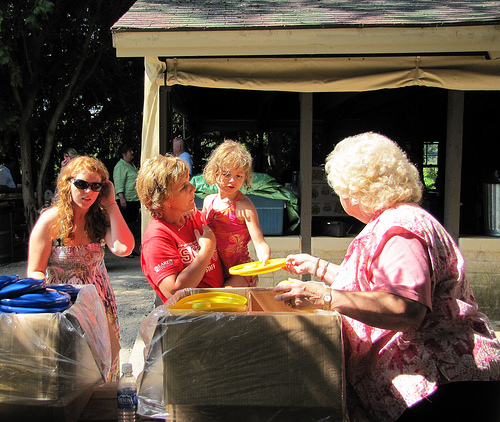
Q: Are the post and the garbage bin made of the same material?
A: No, the post is made of wood and the garbage bin is made of metal.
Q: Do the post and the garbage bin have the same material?
A: No, the post is made of wood and the garbage bin is made of metal.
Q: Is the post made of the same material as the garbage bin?
A: No, the post is made of wood and the garbage bin is made of metal.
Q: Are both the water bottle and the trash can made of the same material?
A: No, the water bottle is made of plastic and the trash can is made of metal.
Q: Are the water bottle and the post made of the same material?
A: No, the water bottle is made of plastic and the post is made of wood.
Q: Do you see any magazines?
A: No, there are no magazines.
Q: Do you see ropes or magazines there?
A: No, there are no magazines or ropes.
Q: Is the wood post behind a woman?
A: Yes, the post is behind a woman.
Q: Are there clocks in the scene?
A: No, there are no clocks.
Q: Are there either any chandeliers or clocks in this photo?
A: No, there are no clocks or chandeliers.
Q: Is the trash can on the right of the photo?
A: Yes, the trash can is on the right of the image.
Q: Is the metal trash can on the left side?
A: No, the garbage can is on the right of the image.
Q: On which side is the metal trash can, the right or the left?
A: The trashcan is on the right of the image.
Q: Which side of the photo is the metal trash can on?
A: The garbage can is on the right of the image.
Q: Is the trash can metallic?
A: Yes, the trash can is metallic.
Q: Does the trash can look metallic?
A: Yes, the trash can is metallic.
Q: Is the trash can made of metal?
A: Yes, the trash can is made of metal.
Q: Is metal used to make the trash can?
A: Yes, the trash can is made of metal.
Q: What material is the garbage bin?
A: The garbage bin is made of metal.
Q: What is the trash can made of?
A: The garbage bin is made of metal.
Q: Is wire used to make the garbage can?
A: No, the garbage can is made of metal.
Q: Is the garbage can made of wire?
A: No, the garbage can is made of metal.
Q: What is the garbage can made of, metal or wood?
A: The garbage can is made of metal.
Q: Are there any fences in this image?
A: No, there are no fences.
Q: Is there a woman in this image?
A: Yes, there is a woman.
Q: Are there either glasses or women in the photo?
A: Yes, there is a woman.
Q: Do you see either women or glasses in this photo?
A: Yes, there is a woman.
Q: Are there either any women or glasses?
A: Yes, there is a woman.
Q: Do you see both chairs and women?
A: No, there is a woman but no chairs.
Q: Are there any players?
A: No, there are no players.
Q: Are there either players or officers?
A: No, there are no players or officers.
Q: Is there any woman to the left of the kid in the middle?
A: Yes, there is a woman to the left of the kid.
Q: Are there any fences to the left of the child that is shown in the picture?
A: No, there is a woman to the left of the child.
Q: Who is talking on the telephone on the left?
A: The woman is talking on the phone.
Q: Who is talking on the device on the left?
A: The woman is talking on the phone.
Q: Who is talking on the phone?
A: The woman is talking on the phone.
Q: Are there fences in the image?
A: No, there are no fences.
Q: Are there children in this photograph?
A: Yes, there is a child.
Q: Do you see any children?
A: Yes, there is a child.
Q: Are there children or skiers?
A: Yes, there is a child.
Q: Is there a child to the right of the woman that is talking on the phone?
A: Yes, there is a child to the right of the woman.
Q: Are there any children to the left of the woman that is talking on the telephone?
A: No, the child is to the right of the woman.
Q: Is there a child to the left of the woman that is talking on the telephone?
A: No, the child is to the right of the woman.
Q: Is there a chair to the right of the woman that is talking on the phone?
A: No, there is a child to the right of the woman.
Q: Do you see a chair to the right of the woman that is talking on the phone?
A: No, there is a child to the right of the woman.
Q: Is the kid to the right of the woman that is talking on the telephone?
A: Yes, the kid is to the right of the woman.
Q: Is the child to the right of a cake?
A: No, the child is to the right of the woman.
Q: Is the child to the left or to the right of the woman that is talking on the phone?
A: The child is to the right of the woman.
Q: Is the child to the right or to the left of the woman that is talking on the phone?
A: The child is to the right of the woman.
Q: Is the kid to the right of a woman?
A: Yes, the kid is to the right of a woman.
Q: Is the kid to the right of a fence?
A: No, the kid is to the right of a woman.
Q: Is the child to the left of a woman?
A: No, the child is to the right of a woman.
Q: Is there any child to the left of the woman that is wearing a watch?
A: Yes, there is a child to the left of the woman.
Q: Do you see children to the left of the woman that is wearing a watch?
A: Yes, there is a child to the left of the woman.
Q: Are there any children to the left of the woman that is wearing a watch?
A: Yes, there is a child to the left of the woman.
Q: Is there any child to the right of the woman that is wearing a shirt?
A: No, the child is to the left of the woman.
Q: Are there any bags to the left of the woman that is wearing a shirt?
A: No, there is a child to the left of the woman.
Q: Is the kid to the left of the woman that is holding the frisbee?
A: Yes, the kid is to the left of the woman.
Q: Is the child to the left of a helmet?
A: No, the child is to the left of the woman.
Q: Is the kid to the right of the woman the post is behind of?
A: No, the kid is to the left of the woman.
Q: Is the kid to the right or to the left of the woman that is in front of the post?
A: The kid is to the left of the woman.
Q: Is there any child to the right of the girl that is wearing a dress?
A: Yes, there is a child to the right of the girl.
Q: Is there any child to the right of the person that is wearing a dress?
A: Yes, there is a child to the right of the girl.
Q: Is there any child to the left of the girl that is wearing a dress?
A: No, the child is to the right of the girl.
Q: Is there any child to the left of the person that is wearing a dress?
A: No, the child is to the right of the girl.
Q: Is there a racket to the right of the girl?
A: No, there is a child to the right of the girl.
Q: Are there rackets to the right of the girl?
A: No, there is a child to the right of the girl.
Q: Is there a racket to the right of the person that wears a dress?
A: No, there is a child to the right of the girl.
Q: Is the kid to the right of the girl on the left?
A: Yes, the kid is to the right of the girl.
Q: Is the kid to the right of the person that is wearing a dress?
A: Yes, the kid is to the right of the girl.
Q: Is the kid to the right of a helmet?
A: No, the kid is to the right of the girl.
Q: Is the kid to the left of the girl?
A: No, the kid is to the right of the girl.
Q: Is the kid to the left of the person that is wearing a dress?
A: No, the kid is to the right of the girl.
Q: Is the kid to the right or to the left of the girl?
A: The kid is to the right of the girl.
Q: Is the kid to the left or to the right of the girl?
A: The kid is to the right of the girl.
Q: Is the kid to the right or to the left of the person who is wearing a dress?
A: The kid is to the right of the girl.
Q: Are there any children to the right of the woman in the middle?
A: Yes, there is a child to the right of the woman.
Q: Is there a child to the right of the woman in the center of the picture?
A: Yes, there is a child to the right of the woman.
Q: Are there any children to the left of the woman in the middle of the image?
A: No, the child is to the right of the woman.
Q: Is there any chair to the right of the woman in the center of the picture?
A: No, there is a child to the right of the woman.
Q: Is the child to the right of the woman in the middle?
A: Yes, the child is to the right of the woman.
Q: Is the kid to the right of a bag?
A: No, the kid is to the right of the woman.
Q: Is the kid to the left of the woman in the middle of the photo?
A: No, the kid is to the right of the woman.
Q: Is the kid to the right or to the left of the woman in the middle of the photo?
A: The kid is to the right of the woman.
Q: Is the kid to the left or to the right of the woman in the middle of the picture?
A: The kid is to the right of the woman.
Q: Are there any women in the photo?
A: Yes, there is a woman.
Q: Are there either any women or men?
A: Yes, there is a woman.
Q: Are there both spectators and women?
A: No, there is a woman but no spectators.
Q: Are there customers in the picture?
A: No, there are no customers.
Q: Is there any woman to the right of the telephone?
A: Yes, there is a woman to the right of the telephone.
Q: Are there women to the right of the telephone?
A: Yes, there is a woman to the right of the telephone.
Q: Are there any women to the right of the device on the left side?
A: Yes, there is a woman to the right of the telephone.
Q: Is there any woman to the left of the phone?
A: No, the woman is to the right of the phone.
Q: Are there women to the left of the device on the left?
A: No, the woman is to the right of the phone.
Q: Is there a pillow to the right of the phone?
A: No, there is a woman to the right of the phone.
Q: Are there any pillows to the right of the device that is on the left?
A: No, there is a woman to the right of the phone.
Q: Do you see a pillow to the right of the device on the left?
A: No, there is a woman to the right of the phone.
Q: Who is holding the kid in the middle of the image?
A: The woman is holding the child.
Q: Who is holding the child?
A: The woman is holding the child.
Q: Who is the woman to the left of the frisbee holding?
A: The woman is holding the child.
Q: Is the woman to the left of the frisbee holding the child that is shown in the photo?
A: Yes, the woman is holding the child.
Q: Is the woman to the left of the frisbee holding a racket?
A: No, the woman is holding the child.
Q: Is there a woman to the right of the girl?
A: Yes, there is a woman to the right of the girl.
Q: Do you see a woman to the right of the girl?
A: Yes, there is a woman to the right of the girl.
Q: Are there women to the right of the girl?
A: Yes, there is a woman to the right of the girl.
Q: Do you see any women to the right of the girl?
A: Yes, there is a woman to the right of the girl.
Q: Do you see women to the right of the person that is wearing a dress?
A: Yes, there is a woman to the right of the girl.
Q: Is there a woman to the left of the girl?
A: No, the woman is to the right of the girl.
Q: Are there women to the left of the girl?
A: No, the woman is to the right of the girl.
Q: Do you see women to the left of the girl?
A: No, the woman is to the right of the girl.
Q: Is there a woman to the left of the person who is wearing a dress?
A: No, the woman is to the right of the girl.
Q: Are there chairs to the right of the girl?
A: No, there is a woman to the right of the girl.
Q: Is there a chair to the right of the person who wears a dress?
A: No, there is a woman to the right of the girl.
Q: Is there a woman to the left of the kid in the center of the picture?
A: Yes, there is a woman to the left of the child.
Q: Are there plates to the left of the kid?
A: No, there is a woman to the left of the kid.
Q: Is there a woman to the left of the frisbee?
A: Yes, there is a woman to the left of the frisbee.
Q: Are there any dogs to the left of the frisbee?
A: No, there is a woman to the left of the frisbee.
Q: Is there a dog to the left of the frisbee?
A: No, there is a woman to the left of the frisbee.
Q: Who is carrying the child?
A: The woman is carrying the child.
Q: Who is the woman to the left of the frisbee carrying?
A: The woman is carrying a kid.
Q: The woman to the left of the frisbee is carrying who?
A: The woman is carrying a kid.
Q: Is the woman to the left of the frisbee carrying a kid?
A: Yes, the woman is carrying a kid.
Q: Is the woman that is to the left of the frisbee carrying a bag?
A: No, the woman is carrying a kid.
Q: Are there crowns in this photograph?
A: No, there are no crowns.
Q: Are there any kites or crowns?
A: No, there are no crowns or kites.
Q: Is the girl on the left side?
A: Yes, the girl is on the left of the image.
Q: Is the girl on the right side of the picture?
A: No, the girl is on the left of the image.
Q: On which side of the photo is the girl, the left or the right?
A: The girl is on the left of the image.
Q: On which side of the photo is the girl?
A: The girl is on the left of the image.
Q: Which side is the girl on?
A: The girl is on the left of the image.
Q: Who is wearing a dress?
A: The girl is wearing a dress.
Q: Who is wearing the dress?
A: The girl is wearing a dress.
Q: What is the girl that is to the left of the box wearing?
A: The girl is wearing a dress.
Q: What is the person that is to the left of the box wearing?
A: The girl is wearing a dress.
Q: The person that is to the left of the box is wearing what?
A: The girl is wearing a dress.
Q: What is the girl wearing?
A: The girl is wearing a dress.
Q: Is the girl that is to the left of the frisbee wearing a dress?
A: Yes, the girl is wearing a dress.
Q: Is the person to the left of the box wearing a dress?
A: Yes, the girl is wearing a dress.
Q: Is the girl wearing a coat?
A: No, the girl is wearing a dress.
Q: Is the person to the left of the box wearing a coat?
A: No, the girl is wearing a dress.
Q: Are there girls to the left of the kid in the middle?
A: Yes, there is a girl to the left of the kid.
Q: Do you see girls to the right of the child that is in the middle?
A: No, the girl is to the left of the kid.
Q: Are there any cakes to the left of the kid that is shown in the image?
A: No, there is a girl to the left of the kid.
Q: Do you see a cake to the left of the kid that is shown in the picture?
A: No, there is a girl to the left of the kid.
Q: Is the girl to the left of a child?
A: Yes, the girl is to the left of a child.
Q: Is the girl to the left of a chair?
A: No, the girl is to the left of a child.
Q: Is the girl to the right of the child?
A: No, the girl is to the left of the child.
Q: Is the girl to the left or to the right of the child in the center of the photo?
A: The girl is to the left of the kid.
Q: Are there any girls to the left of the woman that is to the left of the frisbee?
A: Yes, there is a girl to the left of the woman.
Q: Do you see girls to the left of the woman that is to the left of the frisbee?
A: Yes, there is a girl to the left of the woman.